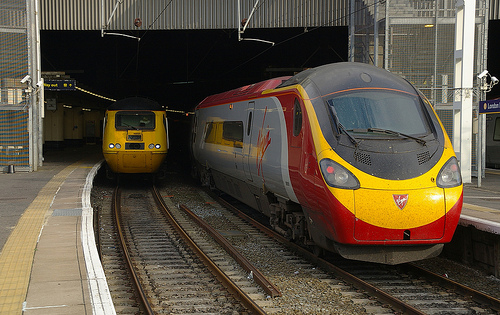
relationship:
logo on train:
[392, 192, 409, 211] [189, 58, 467, 270]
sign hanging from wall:
[45, 96, 58, 113] [28, 96, 102, 147]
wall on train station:
[28, 96, 102, 147] [2, 3, 499, 179]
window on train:
[326, 87, 429, 146] [189, 58, 467, 270]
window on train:
[198, 118, 246, 150] [189, 58, 467, 270]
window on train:
[289, 99, 307, 139] [189, 58, 467, 270]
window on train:
[246, 111, 255, 137] [189, 58, 467, 270]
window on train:
[117, 115, 154, 131] [101, 94, 170, 178]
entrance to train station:
[32, 22, 363, 176] [2, 3, 499, 179]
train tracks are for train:
[109, 173, 266, 314] [101, 94, 170, 178]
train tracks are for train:
[212, 186, 491, 314] [189, 58, 467, 270]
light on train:
[154, 141, 163, 151] [101, 94, 170, 178]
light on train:
[107, 144, 115, 150] [101, 94, 170, 178]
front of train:
[103, 102, 167, 166] [101, 94, 170, 178]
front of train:
[305, 58, 465, 259] [189, 58, 467, 270]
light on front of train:
[154, 141, 163, 151] [101, 94, 170, 178]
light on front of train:
[107, 144, 115, 150] [101, 94, 170, 178]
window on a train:
[326, 87, 429, 146] [189, 58, 467, 270]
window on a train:
[289, 99, 307, 139] [189, 58, 467, 270]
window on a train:
[246, 111, 255, 137] [189, 58, 467, 270]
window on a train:
[198, 118, 246, 150] [189, 58, 467, 270]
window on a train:
[117, 115, 154, 131] [101, 94, 170, 178]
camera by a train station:
[17, 74, 45, 96] [2, 3, 499, 179]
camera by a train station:
[475, 65, 497, 96] [2, 3, 499, 179]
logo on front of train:
[392, 192, 409, 211] [189, 58, 467, 270]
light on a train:
[154, 141, 163, 151] [101, 94, 170, 178]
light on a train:
[107, 144, 115, 150] [101, 94, 170, 178]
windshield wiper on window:
[328, 99, 363, 152] [326, 87, 429, 146]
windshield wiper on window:
[348, 124, 431, 148] [326, 87, 429, 146]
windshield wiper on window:
[118, 118, 137, 133] [117, 115, 154, 131]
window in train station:
[8, 88, 23, 105] [2, 3, 499, 179]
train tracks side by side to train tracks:
[109, 173, 266, 314] [212, 186, 491, 314]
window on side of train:
[246, 111, 255, 137] [189, 58, 467, 270]